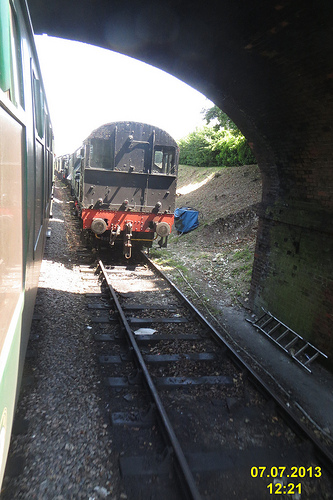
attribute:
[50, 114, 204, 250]
train — black, red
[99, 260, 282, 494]
tracks — black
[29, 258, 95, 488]
rocks — grey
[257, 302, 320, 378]
ladder — black, silver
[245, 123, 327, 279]
wall — white, brown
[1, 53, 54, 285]
fence — dark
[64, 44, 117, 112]
sky — white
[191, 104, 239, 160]
bush — green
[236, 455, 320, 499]
text — yellow